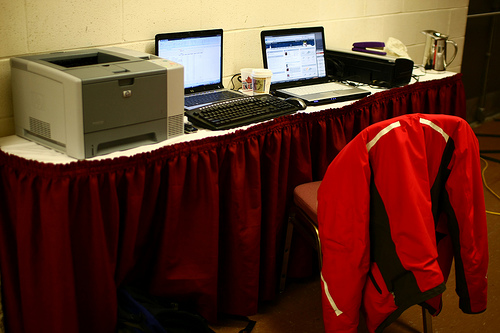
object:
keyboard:
[185, 94, 304, 130]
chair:
[292, 113, 484, 332]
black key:
[207, 115, 212, 117]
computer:
[260, 26, 371, 106]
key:
[209, 109, 214, 113]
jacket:
[315, 112, 490, 332]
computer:
[155, 29, 300, 130]